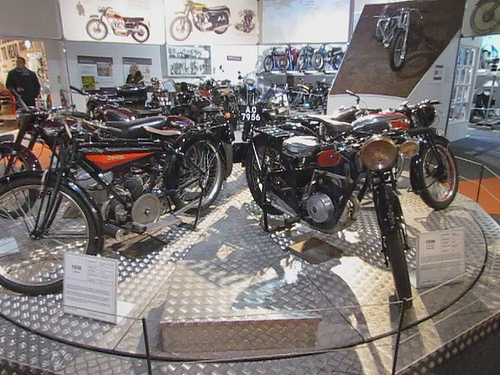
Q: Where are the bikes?
A: In the store.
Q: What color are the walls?
A: White.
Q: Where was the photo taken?
A: Inside of a motorcycle shop.